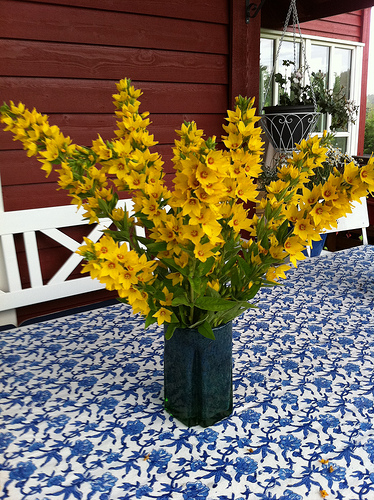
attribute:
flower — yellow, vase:
[84, 140, 292, 276]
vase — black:
[171, 338, 250, 404]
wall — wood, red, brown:
[135, 11, 212, 68]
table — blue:
[294, 303, 345, 345]